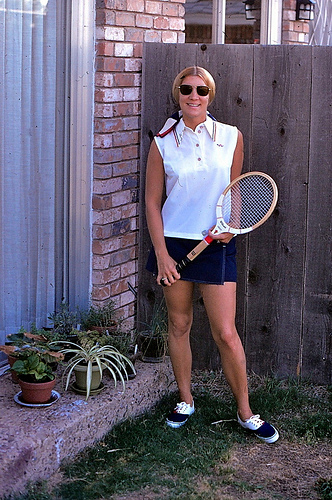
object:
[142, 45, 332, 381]
fence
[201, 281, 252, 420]
left leg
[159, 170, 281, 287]
racket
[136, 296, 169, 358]
potted plants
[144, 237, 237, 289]
skirt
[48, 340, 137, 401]
plants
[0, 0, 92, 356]
door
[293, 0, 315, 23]
light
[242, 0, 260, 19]
reflection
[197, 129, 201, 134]
buttons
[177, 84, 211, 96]
sunglasses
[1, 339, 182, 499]
step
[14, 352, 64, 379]
plant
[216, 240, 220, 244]
ring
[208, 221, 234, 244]
hand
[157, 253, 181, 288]
hand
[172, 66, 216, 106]
hair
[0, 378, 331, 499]
grass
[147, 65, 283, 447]
female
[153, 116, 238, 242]
shirt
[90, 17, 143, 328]
wall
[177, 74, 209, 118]
face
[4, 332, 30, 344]
plants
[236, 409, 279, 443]
shoe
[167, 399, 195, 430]
shoe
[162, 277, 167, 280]
ring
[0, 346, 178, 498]
stoop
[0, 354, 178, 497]
step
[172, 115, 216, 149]
collar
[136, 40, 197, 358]
plank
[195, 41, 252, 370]
plank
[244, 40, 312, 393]
plank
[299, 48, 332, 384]
plank